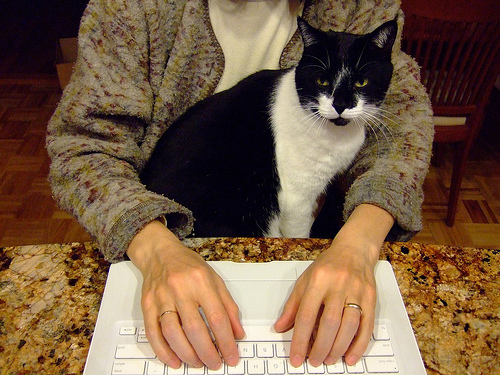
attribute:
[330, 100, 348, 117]
nose — black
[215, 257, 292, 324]
touchpad — white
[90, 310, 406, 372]
keyboard — white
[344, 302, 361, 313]
wedding ring — silver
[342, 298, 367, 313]
ring — left finger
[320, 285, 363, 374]
finger — ring finger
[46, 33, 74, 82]
cardboard box — brown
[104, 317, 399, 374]
laptop keyboard — white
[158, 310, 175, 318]
ring — ring finger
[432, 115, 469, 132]
seat cushion — white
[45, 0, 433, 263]
jacket — multi-colored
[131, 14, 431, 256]
cat — white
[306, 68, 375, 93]
eyes — yellow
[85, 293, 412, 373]
keyboard — white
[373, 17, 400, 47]
ear — white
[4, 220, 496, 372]
table — granite, tan, brown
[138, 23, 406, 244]
cat — black, white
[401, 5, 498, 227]
chair — wooden, dark 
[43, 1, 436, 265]
sweater — gray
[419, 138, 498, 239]
tiles — parquet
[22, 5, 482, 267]
sweater — gray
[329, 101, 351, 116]
nose — white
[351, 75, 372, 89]
eye — white, black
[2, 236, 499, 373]
table — multi-colored, speckled granite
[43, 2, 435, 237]
housecoat — grey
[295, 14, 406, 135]
face — white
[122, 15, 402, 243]
cat — black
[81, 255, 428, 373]
laptop keyboard — white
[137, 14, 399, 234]
cat — black, white, seated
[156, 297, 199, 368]
finger — right finger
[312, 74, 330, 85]
eye — yellow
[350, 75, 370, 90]
eye — yellow